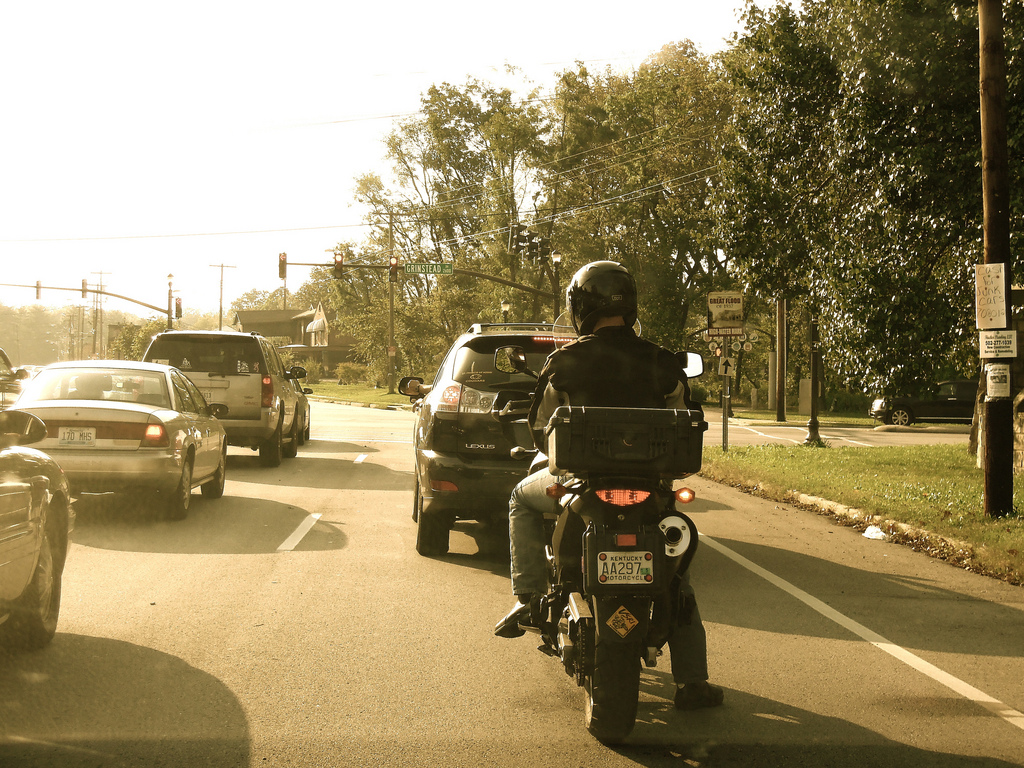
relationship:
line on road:
[879, 580, 957, 768] [0, 398, 1024, 768]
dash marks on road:
[231, 431, 344, 747] [2, 377, 1020, 764]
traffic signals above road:
[112, 104, 947, 174] [0, 398, 1024, 768]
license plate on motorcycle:
[594, 545, 662, 589] [494, 338, 704, 735]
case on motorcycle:
[512, 398, 726, 494] [494, 338, 704, 735]